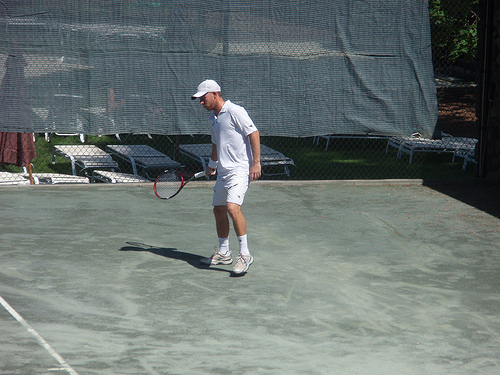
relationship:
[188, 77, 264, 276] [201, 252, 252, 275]
man wearing shoes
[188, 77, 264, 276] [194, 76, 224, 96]
man wearing hat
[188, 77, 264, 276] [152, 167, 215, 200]
man holding racket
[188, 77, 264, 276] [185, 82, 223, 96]
man wearing hat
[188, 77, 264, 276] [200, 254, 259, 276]
man wearing shoes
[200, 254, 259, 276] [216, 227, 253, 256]
shoes wearing socks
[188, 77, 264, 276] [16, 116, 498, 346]
man standing tennis court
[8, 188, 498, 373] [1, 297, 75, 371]
court marked line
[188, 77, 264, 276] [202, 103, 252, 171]
man wearing t-shirt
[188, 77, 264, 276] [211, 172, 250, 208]
man wearing shorts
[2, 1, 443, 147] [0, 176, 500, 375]
net on court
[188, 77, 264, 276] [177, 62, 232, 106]
man wearing hat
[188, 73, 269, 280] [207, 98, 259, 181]
man wearing t-shirt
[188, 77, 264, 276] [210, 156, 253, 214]
man wearing shorts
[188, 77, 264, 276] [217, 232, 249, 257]
man wearing socks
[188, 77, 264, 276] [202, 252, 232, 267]
man wearing shoe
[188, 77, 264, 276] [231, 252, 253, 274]
man wearing shoe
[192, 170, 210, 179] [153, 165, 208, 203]
white grip on racket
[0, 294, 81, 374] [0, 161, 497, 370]
line on court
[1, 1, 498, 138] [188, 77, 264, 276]
tarp behind man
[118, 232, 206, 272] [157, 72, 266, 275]
shadow of person